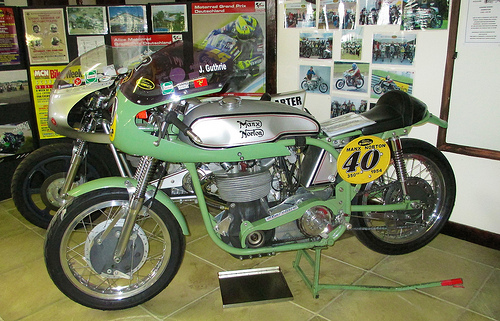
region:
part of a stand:
[296, 259, 332, 294]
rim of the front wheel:
[96, 229, 154, 281]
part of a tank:
[218, 120, 258, 142]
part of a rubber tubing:
[444, 169, 456, 194]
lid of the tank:
[224, 94, 236, 107]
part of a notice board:
[458, 73, 481, 108]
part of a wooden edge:
[462, 145, 490, 161]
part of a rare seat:
[381, 110, 398, 126]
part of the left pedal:
[331, 215, 355, 233]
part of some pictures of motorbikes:
[293, 2, 375, 97]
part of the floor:
[462, 247, 487, 287]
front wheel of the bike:
[63, 222, 165, 293]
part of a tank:
[211, 125, 248, 145]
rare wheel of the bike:
[358, 173, 440, 235]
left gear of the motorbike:
[169, 120, 197, 147]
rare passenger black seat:
[376, 85, 406, 120]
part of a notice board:
[456, 82, 473, 133]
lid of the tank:
[219, 92, 238, 104]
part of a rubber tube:
[46, 232, 61, 257]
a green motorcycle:
[29, 25, 456, 310]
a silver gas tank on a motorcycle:
[160, 97, 330, 151]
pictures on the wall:
[241, 7, 440, 99]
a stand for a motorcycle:
[279, 191, 442, 319]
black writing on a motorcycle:
[181, 97, 293, 152]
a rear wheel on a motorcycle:
[314, 135, 469, 282]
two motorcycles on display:
[57, 38, 447, 318]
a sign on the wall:
[435, 3, 495, 67]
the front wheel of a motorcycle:
[33, 172, 183, 312]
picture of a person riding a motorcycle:
[179, 0, 266, 88]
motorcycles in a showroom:
[40, 7, 478, 305]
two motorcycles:
[20, 39, 497, 318]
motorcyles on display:
[8, 35, 483, 319]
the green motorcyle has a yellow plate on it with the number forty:
[63, 49, 480, 312]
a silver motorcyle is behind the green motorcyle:
[17, 40, 178, 234]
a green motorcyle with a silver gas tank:
[49, 48, 454, 306]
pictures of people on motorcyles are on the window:
[282, 1, 442, 143]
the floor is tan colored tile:
[18, 166, 490, 318]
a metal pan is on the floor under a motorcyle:
[198, 266, 325, 318]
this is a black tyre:
[44, 196, 184, 301]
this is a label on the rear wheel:
[336, 135, 403, 183]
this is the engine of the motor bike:
[214, 162, 289, 216]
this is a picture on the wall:
[23, 7, 70, 64]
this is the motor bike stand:
[293, 240, 378, 320]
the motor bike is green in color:
[110, 83, 355, 248]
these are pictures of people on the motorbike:
[303, 65, 371, 98]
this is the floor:
[6, 265, 49, 320]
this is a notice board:
[435, 0, 499, 160]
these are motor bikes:
[11, 28, 467, 298]